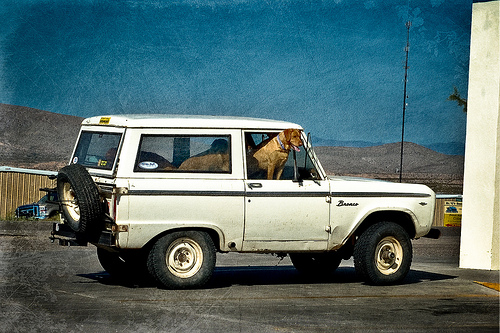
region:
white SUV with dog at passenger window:
[62, 99, 459, 299]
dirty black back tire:
[139, 219, 232, 291]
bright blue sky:
[45, 19, 432, 110]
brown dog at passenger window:
[243, 120, 314, 187]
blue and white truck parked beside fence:
[11, 171, 57, 228]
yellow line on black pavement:
[139, 294, 436, 309]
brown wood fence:
[13, 174, 45, 193]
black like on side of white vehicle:
[126, 183, 423, 202]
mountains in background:
[325, 136, 467, 183]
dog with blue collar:
[266, 120, 308, 187]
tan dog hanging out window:
[252, 128, 304, 176]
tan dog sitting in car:
[180, 136, 235, 175]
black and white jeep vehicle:
[57, 111, 435, 290]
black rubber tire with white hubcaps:
[148, 228, 215, 283]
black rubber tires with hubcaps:
[357, 224, 409, 281]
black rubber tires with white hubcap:
[55, 161, 105, 239]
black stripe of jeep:
[116, 182, 429, 204]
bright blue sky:
[3, 2, 470, 179]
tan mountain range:
[0, 102, 466, 185]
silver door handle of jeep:
[248, 181, 261, 189]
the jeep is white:
[53, 100, 443, 289]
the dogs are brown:
[173, 126, 305, 182]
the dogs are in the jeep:
[164, 122, 337, 202]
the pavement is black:
[0, 214, 499, 331]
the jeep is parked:
[48, 109, 445, 291]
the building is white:
[458, 0, 497, 270]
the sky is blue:
[1, 0, 492, 147]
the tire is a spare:
[41, 150, 121, 246]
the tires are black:
[52, 159, 424, 291]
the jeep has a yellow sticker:
[98, 112, 110, 131]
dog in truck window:
[254, 126, 314, 173]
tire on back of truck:
[49, 155, 115, 245]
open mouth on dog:
[286, 138, 306, 157]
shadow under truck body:
[203, 252, 325, 296]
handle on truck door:
[241, 177, 267, 197]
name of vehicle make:
[329, 190, 367, 214]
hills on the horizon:
[343, 125, 440, 164]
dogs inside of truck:
[120, 138, 236, 167]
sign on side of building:
[432, 195, 466, 230]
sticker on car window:
[133, 151, 167, 178]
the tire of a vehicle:
[153, 223, 218, 293]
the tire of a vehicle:
[357, 217, 409, 279]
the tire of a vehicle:
[48, 160, 107, 246]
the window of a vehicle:
[133, 129, 230, 175]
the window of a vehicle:
[244, 124, 307, 180]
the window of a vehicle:
[69, 122, 125, 169]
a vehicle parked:
[18, 185, 66, 233]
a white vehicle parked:
[53, 90, 440, 296]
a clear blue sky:
[1, 0, 468, 160]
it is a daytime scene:
[0, 0, 498, 328]